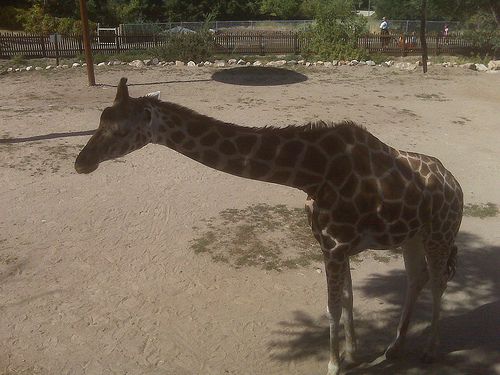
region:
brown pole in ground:
[76, 0, 92, 87]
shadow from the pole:
[193, 66, 309, 94]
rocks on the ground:
[301, 59, 337, 69]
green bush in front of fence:
[315, 29, 367, 55]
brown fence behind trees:
[0, 34, 82, 55]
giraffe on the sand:
[71, 70, 475, 364]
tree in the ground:
[416, 7, 427, 70]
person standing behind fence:
[381, 13, 393, 44]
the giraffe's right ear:
[138, 102, 163, 136]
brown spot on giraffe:
[200, 132, 221, 146]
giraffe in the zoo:
[102, 94, 450, 370]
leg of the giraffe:
[322, 260, 345, 372]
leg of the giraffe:
[339, 291, 359, 363]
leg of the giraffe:
[388, 262, 407, 359]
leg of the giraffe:
[421, 285, 438, 365]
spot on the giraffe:
[330, 160, 351, 185]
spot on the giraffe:
[296, 148, 322, 176]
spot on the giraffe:
[378, 205, 390, 221]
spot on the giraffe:
[340, 201, 356, 221]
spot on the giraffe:
[251, 143, 276, 159]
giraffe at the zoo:
[71, 55, 462, 360]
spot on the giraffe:
[385, 175, 404, 198]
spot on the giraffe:
[335, 205, 351, 220]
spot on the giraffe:
[419, 195, 436, 221]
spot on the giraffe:
[277, 140, 295, 166]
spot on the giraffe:
[234, 135, 251, 155]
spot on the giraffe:
[350, 149, 367, 172]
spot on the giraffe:
[409, 171, 431, 191]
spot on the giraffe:
[427, 198, 444, 212]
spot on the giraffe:
[437, 215, 449, 232]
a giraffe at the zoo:
[73, 76, 465, 373]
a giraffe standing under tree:
[72, 76, 464, 373]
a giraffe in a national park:
[73, 75, 464, 373]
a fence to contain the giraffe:
[0, 29, 499, 59]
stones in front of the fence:
[5, 58, 499, 75]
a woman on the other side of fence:
[377, 15, 390, 48]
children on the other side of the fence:
[397, 22, 453, 49]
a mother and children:
[375, 15, 451, 47]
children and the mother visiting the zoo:
[376, 15, 453, 48]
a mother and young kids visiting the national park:
[377, 15, 453, 48]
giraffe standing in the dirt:
[64, 77, 464, 369]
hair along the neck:
[136, 95, 344, 136]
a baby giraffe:
[76, 81, 463, 373]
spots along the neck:
[162, 110, 324, 199]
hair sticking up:
[279, 115, 343, 130]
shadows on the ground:
[251, 242, 499, 373]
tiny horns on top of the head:
[111, 73, 133, 97]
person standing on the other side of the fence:
[377, 15, 394, 48]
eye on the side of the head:
[115, 122, 132, 141]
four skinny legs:
[305, 241, 462, 374]